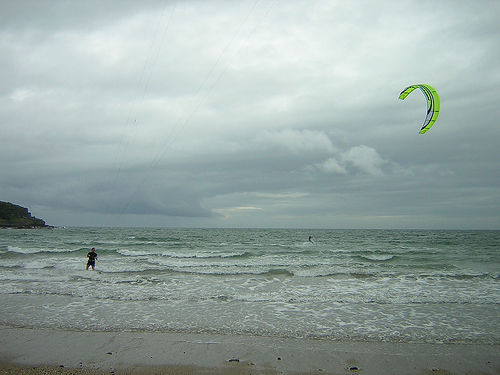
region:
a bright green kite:
[396, 72, 442, 137]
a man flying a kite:
[86, 247, 100, 269]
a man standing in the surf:
[84, 240, 101, 275]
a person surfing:
[306, 231, 318, 247]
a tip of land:
[0, 197, 54, 229]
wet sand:
[3, 315, 499, 373]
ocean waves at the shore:
[5, 245, 499, 340]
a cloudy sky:
[3, 2, 499, 235]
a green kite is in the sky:
[3, 1, 493, 231]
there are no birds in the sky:
[5, 5, 497, 230]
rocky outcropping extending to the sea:
[0, 187, 65, 230]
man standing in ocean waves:
[82, 245, 105, 275]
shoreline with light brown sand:
[0, 318, 497, 373]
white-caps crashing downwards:
[108, 246, 251, 260]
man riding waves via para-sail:
[301, 78, 446, 248]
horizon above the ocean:
[58, 220, 497, 232]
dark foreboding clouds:
[2, 122, 404, 222]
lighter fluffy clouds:
[51, 4, 494, 72]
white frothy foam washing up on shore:
[248, 276, 498, 338]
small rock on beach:
[347, 364, 359, 371]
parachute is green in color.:
[383, 71, 449, 156]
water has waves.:
[123, 237, 312, 291]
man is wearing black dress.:
[85, 250, 105, 274]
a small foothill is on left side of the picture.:
[3, 198, 46, 234]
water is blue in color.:
[109, 233, 209, 271]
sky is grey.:
[80, 162, 237, 212]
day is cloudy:
[73, 173, 158, 207]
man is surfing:
[302, 226, 325, 253]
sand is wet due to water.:
[25, 303, 150, 373]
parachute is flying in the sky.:
[341, 50, 489, 212]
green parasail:
[394, 82, 444, 137]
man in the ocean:
[78, 243, 101, 274]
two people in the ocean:
[81, 230, 324, 273]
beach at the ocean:
[6, 285, 453, 366]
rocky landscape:
[0, 187, 70, 234]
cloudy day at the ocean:
[44, 30, 301, 232]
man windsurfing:
[297, 80, 442, 245]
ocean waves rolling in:
[210, 260, 460, 321]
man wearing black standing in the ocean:
[81, 245, 97, 270]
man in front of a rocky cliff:
[4, 202, 109, 272]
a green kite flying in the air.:
[393, 82, 442, 137]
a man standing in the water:
[78, 245, 100, 272]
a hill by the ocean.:
[3, 200, 48, 230]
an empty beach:
[6, 293, 497, 367]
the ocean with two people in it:
[4, 225, 496, 318]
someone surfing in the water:
[304, 228, 317, 247]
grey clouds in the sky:
[178, 105, 380, 195]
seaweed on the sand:
[221, 355, 255, 368]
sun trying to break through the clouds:
[256, 73, 342, 119]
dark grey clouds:
[446, 140, 498, 222]